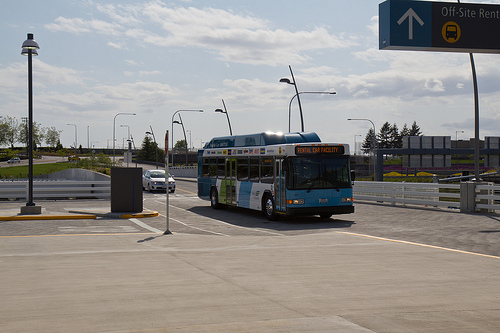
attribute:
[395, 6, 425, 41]
arrow — white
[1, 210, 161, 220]
curb — yellow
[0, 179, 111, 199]
fence — white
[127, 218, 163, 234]
lines — white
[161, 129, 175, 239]
sign — stop sign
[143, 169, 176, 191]
car — white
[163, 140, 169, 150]
word — white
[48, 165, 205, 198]
bridge — cement